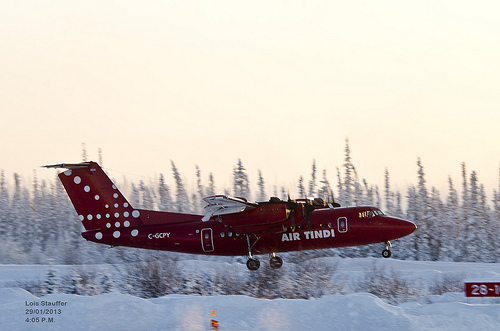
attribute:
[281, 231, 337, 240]
wording — air, white, bold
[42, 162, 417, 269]
airplane — red, landing, flying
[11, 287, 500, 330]
snow — white, piled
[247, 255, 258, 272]
wheels — black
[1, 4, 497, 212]
sky — pink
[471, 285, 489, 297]
number — 28